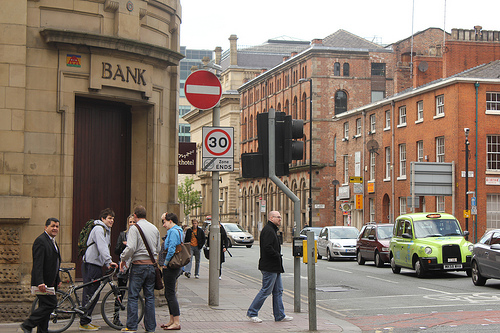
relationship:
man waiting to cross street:
[246, 211, 295, 323] [318, 292, 495, 321]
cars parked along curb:
[468, 229, 500, 285] [324, 309, 367, 331]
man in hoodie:
[75, 208, 117, 330] [80, 217, 115, 268]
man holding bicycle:
[75, 208, 117, 330] [28, 261, 147, 332]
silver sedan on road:
[312, 221, 364, 262] [199, 236, 499, 331]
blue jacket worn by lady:
[161, 216, 184, 255] [157, 212, 187, 328]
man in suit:
[17, 217, 62, 332] [20, 231, 60, 331]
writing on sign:
[185, 122, 247, 169] [173, 98, 257, 203]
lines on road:
[324, 264, 465, 296] [243, 245, 495, 301]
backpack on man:
[78, 220, 93, 255] [74, 209, 116, 319]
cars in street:
[305, 209, 495, 269] [296, 230, 446, 312]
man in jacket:
[205, 199, 392, 329] [256, 222, 286, 274]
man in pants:
[205, 199, 392, 329] [246, 270, 288, 318]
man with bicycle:
[75, 208, 117, 330] [28, 267, 147, 332]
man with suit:
[246, 211, 295, 323] [30, 232, 57, 322]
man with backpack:
[74, 204, 118, 327] [74, 220, 93, 255]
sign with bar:
[172, 51, 246, 129] [187, 84, 222, 94]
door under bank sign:
[71, 92, 131, 279] [100, 60, 145, 86]